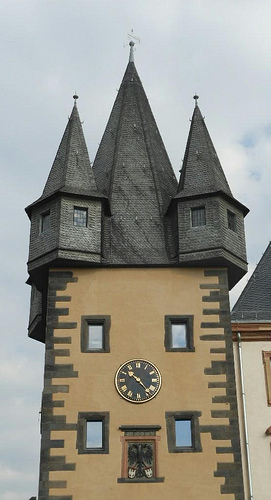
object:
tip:
[193, 93, 199, 108]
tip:
[73, 91, 79, 103]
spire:
[177, 92, 233, 197]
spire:
[92, 28, 180, 259]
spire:
[42, 91, 98, 197]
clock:
[115, 358, 162, 403]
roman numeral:
[145, 388, 152, 396]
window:
[81, 315, 110, 352]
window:
[164, 314, 194, 351]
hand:
[128, 371, 137, 379]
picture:
[0, 0, 271, 500]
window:
[42, 213, 50, 233]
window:
[73, 209, 87, 228]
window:
[192, 208, 204, 227]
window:
[228, 212, 235, 232]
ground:
[209, 62, 220, 77]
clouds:
[235, 125, 267, 186]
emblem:
[118, 425, 161, 479]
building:
[230, 241, 271, 500]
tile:
[114, 171, 140, 216]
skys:
[0, 1, 271, 500]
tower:
[25, 29, 250, 500]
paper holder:
[115, 359, 162, 404]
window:
[77, 411, 109, 453]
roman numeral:
[144, 364, 148, 371]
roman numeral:
[136, 362, 141, 369]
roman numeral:
[149, 370, 155, 376]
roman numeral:
[149, 384, 156, 391]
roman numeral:
[136, 393, 141, 399]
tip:
[123, 29, 140, 63]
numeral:
[119, 378, 125, 382]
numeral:
[126, 363, 132, 370]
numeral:
[127, 390, 133, 397]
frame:
[77, 411, 109, 454]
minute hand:
[139, 379, 150, 392]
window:
[165, 411, 199, 453]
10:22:
[120, 364, 153, 398]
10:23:
[118, 363, 153, 401]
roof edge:
[58, 185, 108, 199]